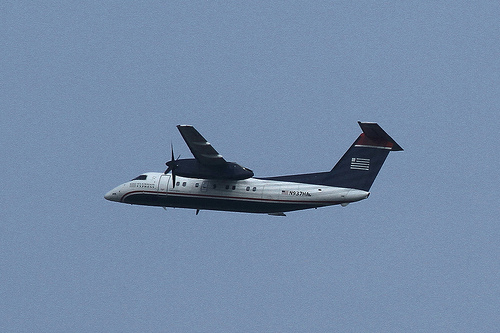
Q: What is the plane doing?
A: Flying.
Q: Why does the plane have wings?
A: To be able to fly.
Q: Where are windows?
A: On the plane.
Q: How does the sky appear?
A: Clear and blue.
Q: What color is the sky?
A: Blue.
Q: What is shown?
A: Airplane.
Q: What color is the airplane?
A: Blue and grey.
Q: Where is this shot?
A: Sky.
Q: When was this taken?
A: Daytime.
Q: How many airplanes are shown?
A: 1.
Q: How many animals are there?
A: 0.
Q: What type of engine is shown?
A: Propeller.